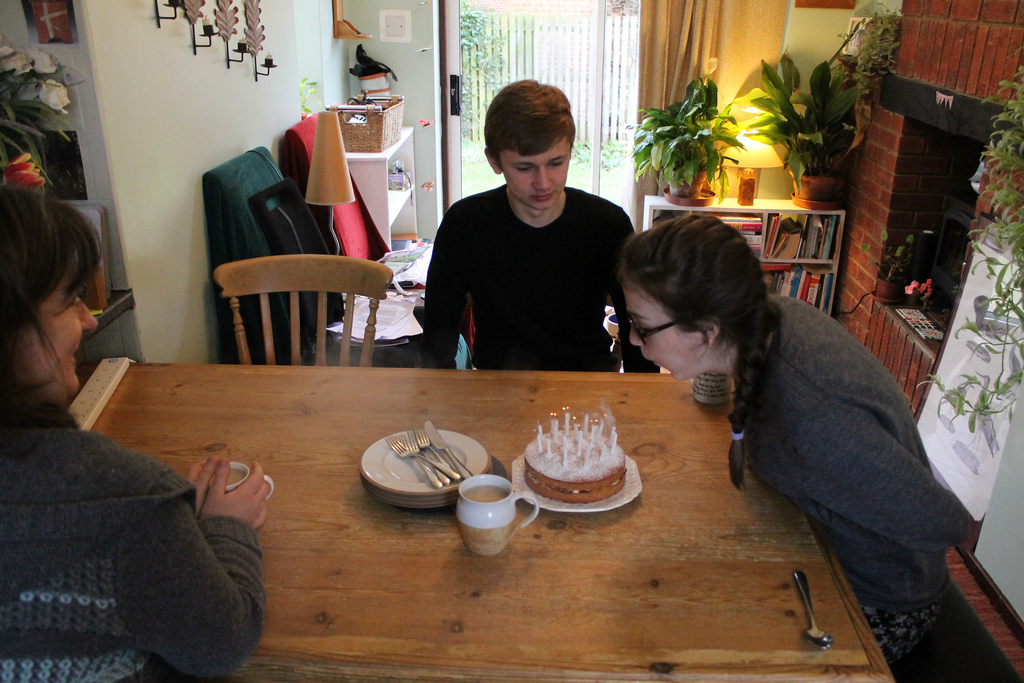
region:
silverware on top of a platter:
[337, 401, 497, 516]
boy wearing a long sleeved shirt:
[393, 59, 687, 396]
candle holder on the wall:
[98, 0, 317, 109]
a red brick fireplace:
[794, 3, 1019, 465]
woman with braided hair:
[599, 189, 970, 592]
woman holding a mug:
[0, 161, 315, 678]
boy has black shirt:
[348, 186, 643, 382]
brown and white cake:
[471, 344, 667, 531]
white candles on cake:
[503, 414, 643, 481]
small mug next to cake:
[441, 481, 546, 589]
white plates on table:
[351, 391, 508, 546]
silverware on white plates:
[333, 420, 514, 537]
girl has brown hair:
[596, 224, 780, 434]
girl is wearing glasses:
[623, 285, 716, 404]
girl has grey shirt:
[620, 297, 933, 642]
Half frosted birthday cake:
[514, 404, 642, 513]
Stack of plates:
[358, 427, 492, 510]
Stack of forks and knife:
[390, 424, 467, 489]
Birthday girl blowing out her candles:
[623, 214, 950, 652]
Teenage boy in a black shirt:
[421, 86, 634, 372]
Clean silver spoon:
[791, 569, 831, 646]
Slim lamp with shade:
[302, 110, 351, 256]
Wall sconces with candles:
[155, 0, 276, 81]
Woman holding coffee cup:
[1, 181, 261, 673]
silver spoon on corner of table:
[789, 560, 829, 646]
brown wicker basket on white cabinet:
[335, 86, 403, 154]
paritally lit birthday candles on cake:
[531, 399, 621, 475]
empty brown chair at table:
[215, 253, 393, 367]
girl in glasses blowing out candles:
[618, 209, 973, 661]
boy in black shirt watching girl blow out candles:
[423, 78, 639, 373]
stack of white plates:
[359, 426, 490, 509]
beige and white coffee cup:
[457, 471, 538, 555]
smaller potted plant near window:
[635, 78, 738, 209]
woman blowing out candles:
[631, 199, 955, 634]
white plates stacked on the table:
[356, 418, 486, 505]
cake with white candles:
[514, 392, 642, 506]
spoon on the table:
[784, 561, 827, 641]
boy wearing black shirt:
[407, 55, 648, 363]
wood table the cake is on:
[104, 358, 891, 679]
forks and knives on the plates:
[385, 409, 468, 489]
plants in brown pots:
[638, 47, 854, 218]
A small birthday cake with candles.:
[510, 393, 641, 518]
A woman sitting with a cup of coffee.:
[2, 158, 293, 680]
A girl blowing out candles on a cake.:
[509, 202, 975, 665]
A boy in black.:
[413, 77, 657, 375]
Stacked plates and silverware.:
[352, 418, 489, 516]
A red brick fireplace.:
[825, 3, 1022, 428]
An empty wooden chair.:
[206, 241, 394, 365]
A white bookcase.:
[642, 186, 849, 317]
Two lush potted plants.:
[636, 37, 865, 214]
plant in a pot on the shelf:
[633, 75, 733, 209]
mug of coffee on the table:
[452, 470, 514, 570]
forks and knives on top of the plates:
[381, 411, 470, 492]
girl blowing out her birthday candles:
[608, 206, 844, 440]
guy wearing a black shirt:
[430, 69, 627, 355]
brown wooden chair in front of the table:
[212, 256, 393, 365]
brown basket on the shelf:
[336, 102, 400, 150]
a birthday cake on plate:
[520, 395, 660, 516]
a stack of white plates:
[350, 392, 496, 507]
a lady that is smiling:
[0, 164, 309, 678]